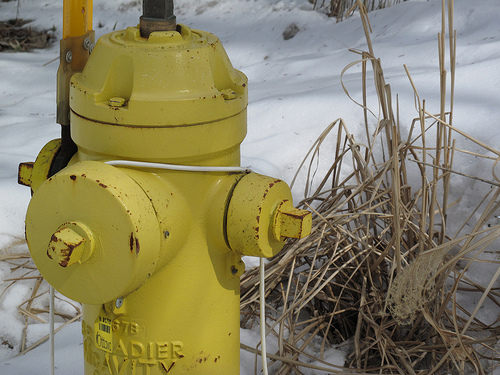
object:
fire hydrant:
[14, 22, 311, 373]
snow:
[0, 1, 500, 374]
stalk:
[290, 118, 347, 191]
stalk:
[357, 58, 380, 171]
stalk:
[407, 158, 499, 188]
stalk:
[424, 108, 500, 157]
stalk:
[404, 63, 428, 138]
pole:
[55, 0, 97, 125]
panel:
[53, 30, 96, 128]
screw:
[83, 38, 97, 50]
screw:
[65, 50, 74, 64]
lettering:
[167, 341, 185, 362]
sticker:
[93, 314, 114, 356]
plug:
[138, 0, 177, 41]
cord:
[96, 157, 251, 176]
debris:
[0, 18, 59, 54]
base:
[46, 128, 78, 179]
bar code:
[97, 321, 110, 334]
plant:
[387, 243, 458, 323]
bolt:
[106, 96, 127, 108]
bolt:
[221, 86, 241, 101]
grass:
[2, 275, 42, 283]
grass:
[1, 231, 24, 243]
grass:
[19, 273, 42, 353]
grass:
[1, 254, 31, 261]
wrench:
[46, 0, 92, 181]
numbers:
[111, 319, 121, 333]